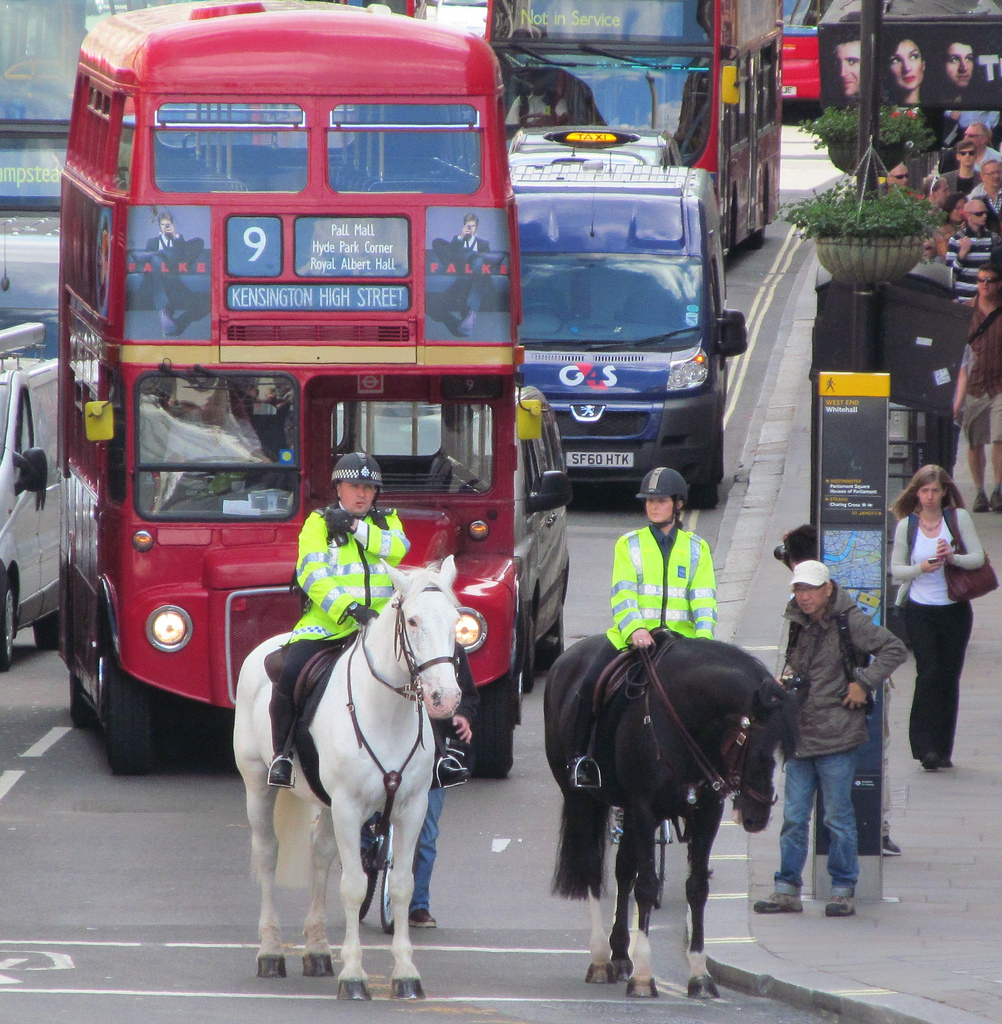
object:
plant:
[785, 191, 931, 243]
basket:
[815, 143, 921, 286]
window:
[150, 95, 313, 194]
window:
[322, 101, 484, 192]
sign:
[216, 205, 416, 317]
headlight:
[146, 602, 192, 652]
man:
[267, 454, 412, 791]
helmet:
[331, 451, 385, 488]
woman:
[566, 458, 722, 786]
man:
[764, 558, 906, 915]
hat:
[788, 560, 832, 585]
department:
[359, 466, 372, 477]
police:
[257, 443, 474, 784]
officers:
[264, 451, 458, 796]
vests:
[290, 501, 401, 643]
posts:
[808, 368, 889, 857]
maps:
[822, 528, 885, 630]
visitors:
[758, 550, 889, 931]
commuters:
[896, 465, 970, 769]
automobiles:
[61, 9, 520, 770]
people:
[954, 260, 1001, 515]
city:
[9, 5, 1002, 1024]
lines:
[20, 720, 66, 763]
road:
[12, 774, 656, 1016]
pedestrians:
[751, 559, 904, 919]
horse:
[227, 559, 462, 1006]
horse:
[538, 629, 794, 1000]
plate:
[566, 440, 636, 470]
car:
[507, 136, 739, 518]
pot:
[785, 179, 933, 288]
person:
[561, 458, 751, 785]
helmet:
[636, 467, 690, 512]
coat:
[610, 523, 720, 646]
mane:
[405, 562, 455, 603]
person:
[765, 559, 899, 929]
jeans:
[769, 737, 859, 908]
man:
[782, 553, 900, 921]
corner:
[677, 704, 1001, 1024]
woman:
[886, 462, 980, 771]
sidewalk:
[698, 232, 991, 1015]